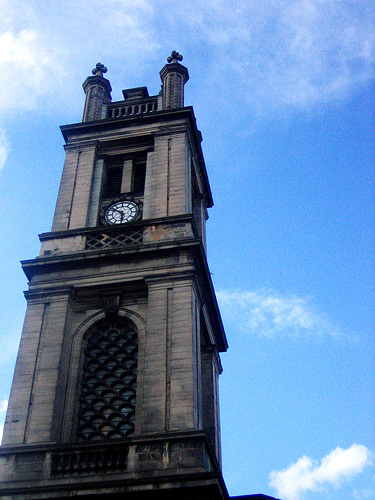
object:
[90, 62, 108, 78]
artwork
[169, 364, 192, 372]
stone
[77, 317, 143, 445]
window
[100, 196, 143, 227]
clock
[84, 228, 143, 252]
hatch pattern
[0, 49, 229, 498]
clock tower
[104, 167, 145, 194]
room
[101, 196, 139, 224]
clock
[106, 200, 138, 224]
clock face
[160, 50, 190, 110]
post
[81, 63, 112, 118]
post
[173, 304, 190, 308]
brick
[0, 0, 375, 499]
cloud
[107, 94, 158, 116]
brick fence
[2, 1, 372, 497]
sky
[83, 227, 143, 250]
metal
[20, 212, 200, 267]
ledge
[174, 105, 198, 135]
corner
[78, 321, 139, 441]
scale detail